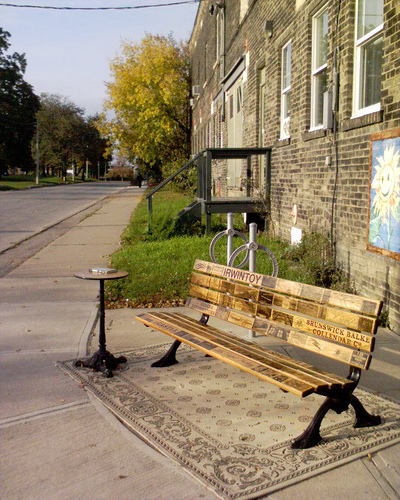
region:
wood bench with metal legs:
[148, 255, 386, 444]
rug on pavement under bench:
[58, 337, 394, 493]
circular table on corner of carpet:
[72, 262, 129, 377]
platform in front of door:
[193, 186, 267, 219]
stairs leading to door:
[153, 190, 213, 236]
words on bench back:
[297, 320, 369, 346]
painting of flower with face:
[365, 147, 395, 223]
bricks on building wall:
[274, 159, 311, 196]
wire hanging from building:
[69, 1, 151, 21]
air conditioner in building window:
[182, 74, 204, 105]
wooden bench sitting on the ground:
[138, 253, 385, 445]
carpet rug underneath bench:
[49, 338, 399, 495]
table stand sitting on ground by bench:
[64, 263, 138, 383]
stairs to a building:
[143, 139, 277, 240]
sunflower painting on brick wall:
[353, 117, 398, 271]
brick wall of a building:
[280, 150, 363, 221]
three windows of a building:
[274, 106, 389, 142]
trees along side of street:
[29, 105, 106, 185]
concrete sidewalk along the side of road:
[67, 195, 124, 255]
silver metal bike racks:
[203, 205, 281, 279]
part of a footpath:
[86, 218, 117, 248]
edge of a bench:
[230, 360, 309, 400]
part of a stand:
[87, 296, 109, 347]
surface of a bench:
[230, 266, 290, 304]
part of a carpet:
[194, 418, 256, 471]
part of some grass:
[143, 245, 185, 281]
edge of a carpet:
[151, 441, 192, 479]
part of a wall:
[306, 160, 351, 204]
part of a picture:
[357, 148, 381, 193]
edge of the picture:
[366, 184, 372, 238]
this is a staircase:
[164, 142, 268, 215]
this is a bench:
[141, 281, 387, 389]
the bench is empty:
[132, 284, 385, 390]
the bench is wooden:
[132, 289, 384, 397]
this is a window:
[308, 5, 331, 127]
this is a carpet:
[164, 400, 272, 458]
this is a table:
[74, 257, 122, 361]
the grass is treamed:
[138, 234, 184, 289]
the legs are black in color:
[298, 393, 375, 453]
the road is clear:
[25, 187, 85, 224]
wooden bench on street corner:
[51, 218, 368, 440]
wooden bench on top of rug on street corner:
[85, 313, 374, 465]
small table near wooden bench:
[58, 239, 139, 390]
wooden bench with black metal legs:
[274, 361, 376, 462]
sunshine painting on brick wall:
[340, 109, 394, 274]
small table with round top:
[62, 259, 138, 294]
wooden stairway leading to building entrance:
[125, 119, 273, 233]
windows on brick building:
[262, 26, 389, 135]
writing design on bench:
[165, 266, 376, 378]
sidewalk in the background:
[33, 145, 138, 253]